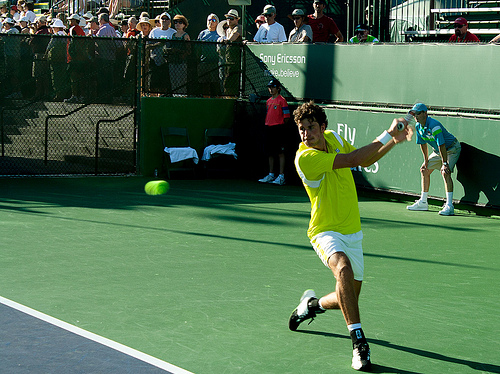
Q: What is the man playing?
A: Tennis.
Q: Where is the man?
A: Tennis court.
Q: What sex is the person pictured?
A: Male.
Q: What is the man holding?
A: Tennis racket.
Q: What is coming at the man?
A: Tennis ball.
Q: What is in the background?
A: Fans.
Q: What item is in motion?
A: The ball.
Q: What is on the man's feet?
A: The shoes.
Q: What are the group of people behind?
A: A gate.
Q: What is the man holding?
A: A tennis racket.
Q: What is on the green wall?
A: The writing.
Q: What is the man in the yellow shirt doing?
A: Playing tennis.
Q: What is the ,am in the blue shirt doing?
A: Resting his back on the wall.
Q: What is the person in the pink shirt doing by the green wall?
A: Standing there.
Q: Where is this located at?
A: A tennis court.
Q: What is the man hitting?
A: Tennis ball.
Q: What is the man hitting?
A: Tennis ball.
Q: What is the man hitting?
A: Tennis ball.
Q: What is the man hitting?
A: Ball.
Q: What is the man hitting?
A: Ball.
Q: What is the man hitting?
A: Ball.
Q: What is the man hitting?
A: Ball.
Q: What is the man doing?
A: Playing tennis.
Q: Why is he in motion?
A: To hit the ball.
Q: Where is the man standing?
A: In the tennis court.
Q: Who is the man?
A: A tennis player.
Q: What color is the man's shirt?
A: Yellow.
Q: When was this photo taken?
A: During the day.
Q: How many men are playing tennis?
A: 1.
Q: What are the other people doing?
A: Spectating.